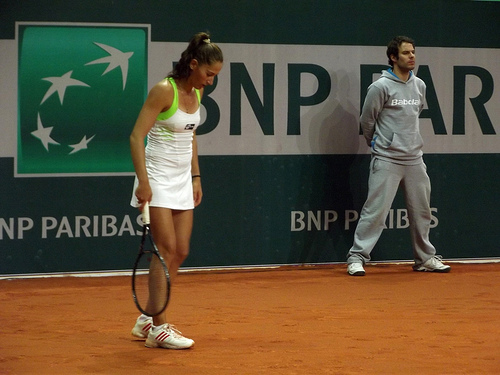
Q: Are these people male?
A: No, they are both male and female.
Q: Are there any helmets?
A: No, there are no helmets.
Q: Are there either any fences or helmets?
A: No, there are no helmets or fences.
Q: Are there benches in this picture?
A: No, there are no benches.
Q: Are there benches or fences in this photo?
A: No, there are no benches or fences.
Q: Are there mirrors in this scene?
A: No, there are no mirrors.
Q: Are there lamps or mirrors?
A: No, there are no mirrors or lamps.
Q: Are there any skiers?
A: No, there are no skiers.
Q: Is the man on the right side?
A: Yes, the man is on the right of the image.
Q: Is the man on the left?
A: No, the man is on the right of the image.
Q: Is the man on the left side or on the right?
A: The man is on the right of the image.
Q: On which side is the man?
A: The man is on the right of the image.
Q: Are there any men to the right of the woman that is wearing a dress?
A: Yes, there is a man to the right of the woman.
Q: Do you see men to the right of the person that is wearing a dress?
A: Yes, there is a man to the right of the woman.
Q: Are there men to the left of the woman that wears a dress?
A: No, the man is to the right of the woman.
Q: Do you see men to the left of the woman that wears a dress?
A: No, the man is to the right of the woman.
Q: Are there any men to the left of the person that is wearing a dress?
A: No, the man is to the right of the woman.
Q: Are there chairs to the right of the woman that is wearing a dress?
A: No, there is a man to the right of the woman.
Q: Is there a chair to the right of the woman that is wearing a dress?
A: No, there is a man to the right of the woman.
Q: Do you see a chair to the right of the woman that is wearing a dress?
A: No, there is a man to the right of the woman.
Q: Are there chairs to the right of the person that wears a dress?
A: No, there is a man to the right of the woman.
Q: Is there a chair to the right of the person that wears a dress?
A: No, there is a man to the right of the woman.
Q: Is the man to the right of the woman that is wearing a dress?
A: Yes, the man is to the right of the woman.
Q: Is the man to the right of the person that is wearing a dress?
A: Yes, the man is to the right of the woman.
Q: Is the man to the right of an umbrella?
A: No, the man is to the right of the woman.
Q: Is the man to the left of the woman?
A: No, the man is to the right of the woman.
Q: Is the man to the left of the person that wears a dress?
A: No, the man is to the right of the woman.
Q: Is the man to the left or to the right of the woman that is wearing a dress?
A: The man is to the right of the woman.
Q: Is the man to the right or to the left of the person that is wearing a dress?
A: The man is to the right of the woman.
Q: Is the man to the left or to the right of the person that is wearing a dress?
A: The man is to the right of the woman.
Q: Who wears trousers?
A: The man wears trousers.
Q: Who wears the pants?
A: The man wears trousers.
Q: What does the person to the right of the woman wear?
A: The man wears pants.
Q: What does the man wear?
A: The man wears pants.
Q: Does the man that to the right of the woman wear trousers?
A: Yes, the man wears trousers.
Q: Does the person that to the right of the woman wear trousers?
A: Yes, the man wears trousers.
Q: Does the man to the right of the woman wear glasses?
A: No, the man wears trousers.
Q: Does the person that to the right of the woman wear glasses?
A: No, the man wears trousers.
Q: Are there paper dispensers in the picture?
A: No, there are no paper dispensers.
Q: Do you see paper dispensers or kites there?
A: No, there are no paper dispensers or kites.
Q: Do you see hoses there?
A: No, there are no hoses.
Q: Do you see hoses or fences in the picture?
A: No, there are no hoses or fences.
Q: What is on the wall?
A: The letter is on the wall.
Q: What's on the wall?
A: The letter is on the wall.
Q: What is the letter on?
A: The letter is on the wall.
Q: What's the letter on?
A: The letter is on the wall.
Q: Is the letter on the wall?
A: Yes, the letter is on the wall.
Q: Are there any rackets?
A: Yes, there is a racket.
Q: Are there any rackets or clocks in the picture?
A: Yes, there is a racket.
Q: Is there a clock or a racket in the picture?
A: Yes, there is a racket.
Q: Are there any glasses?
A: No, there are no glasses.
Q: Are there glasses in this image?
A: No, there are no glasses.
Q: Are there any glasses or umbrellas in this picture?
A: No, there are no glasses or umbrellas.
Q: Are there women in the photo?
A: Yes, there is a woman.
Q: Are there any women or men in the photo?
A: Yes, there is a woman.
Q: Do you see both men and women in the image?
A: Yes, there are both a woman and a man.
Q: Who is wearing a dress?
A: The woman is wearing a dress.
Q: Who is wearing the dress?
A: The woman is wearing a dress.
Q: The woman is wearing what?
A: The woman is wearing a dress.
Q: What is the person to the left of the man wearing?
A: The woman is wearing a dress.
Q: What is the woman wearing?
A: The woman is wearing a dress.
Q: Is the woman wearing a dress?
A: Yes, the woman is wearing a dress.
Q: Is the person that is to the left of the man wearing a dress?
A: Yes, the woman is wearing a dress.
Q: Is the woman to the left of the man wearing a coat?
A: No, the woman is wearing a dress.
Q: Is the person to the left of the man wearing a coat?
A: No, the woman is wearing a dress.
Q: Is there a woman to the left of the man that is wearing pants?
A: Yes, there is a woman to the left of the man.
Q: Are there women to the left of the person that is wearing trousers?
A: Yes, there is a woman to the left of the man.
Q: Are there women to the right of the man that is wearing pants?
A: No, the woman is to the left of the man.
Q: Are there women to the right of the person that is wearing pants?
A: No, the woman is to the left of the man.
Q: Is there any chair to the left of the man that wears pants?
A: No, there is a woman to the left of the man.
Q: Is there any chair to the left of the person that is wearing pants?
A: No, there is a woman to the left of the man.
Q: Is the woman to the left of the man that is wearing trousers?
A: Yes, the woman is to the left of the man.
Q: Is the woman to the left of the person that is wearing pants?
A: Yes, the woman is to the left of the man.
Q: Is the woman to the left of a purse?
A: No, the woman is to the left of the man.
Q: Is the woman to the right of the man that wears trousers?
A: No, the woman is to the left of the man.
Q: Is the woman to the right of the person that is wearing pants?
A: No, the woman is to the left of the man.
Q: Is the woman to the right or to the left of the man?
A: The woman is to the left of the man.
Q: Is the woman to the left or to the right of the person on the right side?
A: The woman is to the left of the man.